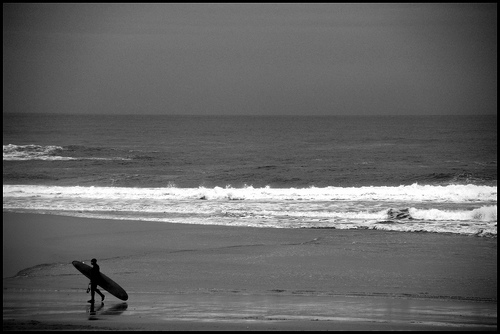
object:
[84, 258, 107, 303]
man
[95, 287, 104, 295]
leg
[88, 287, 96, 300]
leg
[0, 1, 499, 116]
sky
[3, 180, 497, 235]
wave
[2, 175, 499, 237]
foam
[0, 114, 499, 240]
water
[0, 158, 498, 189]
ripples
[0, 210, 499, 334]
sand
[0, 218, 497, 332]
beach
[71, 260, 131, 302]
surfboard